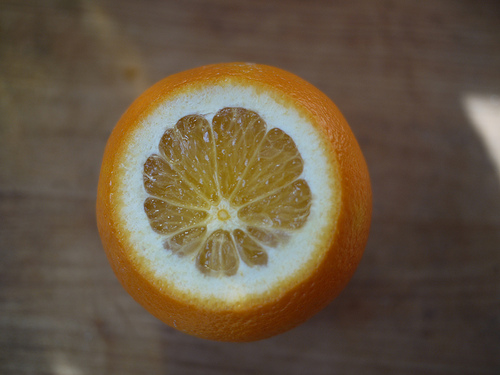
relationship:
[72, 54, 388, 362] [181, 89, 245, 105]
orange has skin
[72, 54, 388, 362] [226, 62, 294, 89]
orange has skin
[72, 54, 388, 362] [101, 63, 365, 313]
orange cut off top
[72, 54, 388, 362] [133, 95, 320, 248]
orange has inside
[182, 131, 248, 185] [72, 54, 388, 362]
light reflects on orange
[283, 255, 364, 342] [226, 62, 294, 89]
shadow on skin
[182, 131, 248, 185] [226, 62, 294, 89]
light reflecting on skin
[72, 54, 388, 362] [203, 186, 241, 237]
orange has inner core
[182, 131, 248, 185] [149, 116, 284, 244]
light reflecting on surface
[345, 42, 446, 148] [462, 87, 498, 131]
table has side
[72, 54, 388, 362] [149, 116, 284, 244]
orange has surface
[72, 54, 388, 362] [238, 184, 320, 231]
orange has slice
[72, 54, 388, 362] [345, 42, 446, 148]
orange on table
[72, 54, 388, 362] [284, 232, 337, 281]
orange has rind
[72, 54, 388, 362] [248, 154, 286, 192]
orange has pulp